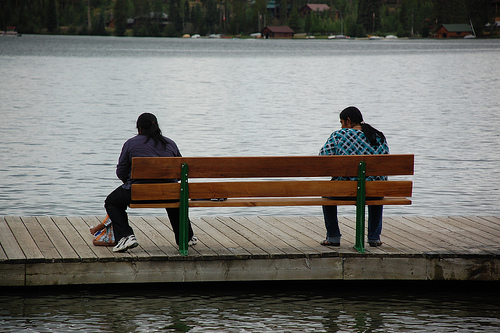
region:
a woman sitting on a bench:
[312, 99, 391, 252]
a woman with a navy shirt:
[101, 101, 199, 254]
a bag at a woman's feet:
[86, 207, 122, 248]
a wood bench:
[116, 145, 417, 253]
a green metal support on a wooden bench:
[168, 157, 192, 253]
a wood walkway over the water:
[1, 207, 497, 287]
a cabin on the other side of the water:
[256, 18, 296, 43]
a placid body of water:
[4, 34, 499, 215]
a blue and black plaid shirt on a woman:
[317, 116, 400, 194]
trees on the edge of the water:
[310, 12, 348, 41]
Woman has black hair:
[127, 111, 168, 136]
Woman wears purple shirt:
[119, 137, 142, 157]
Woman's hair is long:
[140, 127, 170, 152]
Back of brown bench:
[133, 154, 418, 211]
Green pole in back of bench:
[178, 158, 190, 255]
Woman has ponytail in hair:
[339, 102, 389, 149]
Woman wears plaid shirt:
[328, 135, 365, 153]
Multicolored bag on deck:
[86, 214, 118, 249]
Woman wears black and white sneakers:
[113, 236, 139, 256]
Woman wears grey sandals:
[309, 229, 347, 254]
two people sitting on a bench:
[81, 106, 427, 253]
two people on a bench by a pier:
[68, 99, 422, 259]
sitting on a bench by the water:
[72, 104, 212, 266]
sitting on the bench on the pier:
[309, 95, 420, 274]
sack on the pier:
[80, 210, 152, 265]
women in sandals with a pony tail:
[308, 90, 408, 270]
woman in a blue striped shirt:
[311, 100, 431, 262]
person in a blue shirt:
[78, 105, 214, 277]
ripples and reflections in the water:
[131, 294, 418, 331]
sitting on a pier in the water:
[69, 93, 426, 290]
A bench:
[256, 87, 430, 250]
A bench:
[138, 106, 359, 276]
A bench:
[192, 168, 414, 306]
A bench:
[93, 29, 313, 267]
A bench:
[151, 55, 380, 218]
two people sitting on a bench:
[51, 66, 436, 261]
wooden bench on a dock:
[129, 151, 432, 252]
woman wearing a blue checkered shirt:
[311, 96, 399, 253]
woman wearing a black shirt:
[89, 91, 207, 267]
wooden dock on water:
[14, 193, 485, 332]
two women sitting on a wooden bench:
[79, 89, 447, 265]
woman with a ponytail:
[315, 98, 401, 257]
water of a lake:
[35, 78, 90, 203]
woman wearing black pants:
[96, 103, 206, 263]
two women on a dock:
[82, 88, 419, 278]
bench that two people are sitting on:
[125, 153, 415, 258]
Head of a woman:
[334, 105, 364, 131]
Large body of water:
[211, 71, 291, 111]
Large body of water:
[181, 302, 283, 331]